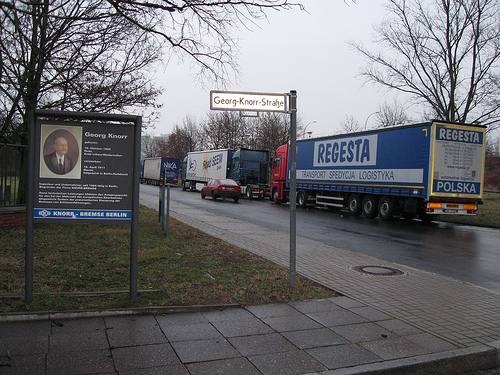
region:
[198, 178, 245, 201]
car on street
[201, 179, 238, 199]
red car on street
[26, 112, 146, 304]
sign on grass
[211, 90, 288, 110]
street sign on corner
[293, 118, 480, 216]
trailer on 18 wheeler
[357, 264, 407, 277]
man hole in ground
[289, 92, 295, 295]
street sign pole on corner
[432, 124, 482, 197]
back of 18 wheeler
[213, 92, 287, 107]
white street sign on corner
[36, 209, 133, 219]
blue color on sign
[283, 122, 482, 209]
blue and white trailer of truck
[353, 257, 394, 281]
manhole cover on sidewalk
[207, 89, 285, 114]
black lettering on white street sign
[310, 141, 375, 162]
blue lettering on white background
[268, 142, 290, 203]
red cab of truck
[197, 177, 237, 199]
red car driving down the road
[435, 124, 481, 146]
white lettering on blue background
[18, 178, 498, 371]
sidewalk along the street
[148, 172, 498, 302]
streets trucks and car are on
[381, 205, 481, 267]
reflection of truck on street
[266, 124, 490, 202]
a red and blue semi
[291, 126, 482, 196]
a blue and white trailer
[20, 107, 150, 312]
a brown and white sign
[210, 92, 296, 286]
a sign on a pole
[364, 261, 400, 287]
a man hole cover on the ground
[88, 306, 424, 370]
a wet side walk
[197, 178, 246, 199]
a red car on the street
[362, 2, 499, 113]
a leafless tree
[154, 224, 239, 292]
green and brown grass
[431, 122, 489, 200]
a yellow edge on a door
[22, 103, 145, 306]
Sign with the history of Georg Knorr.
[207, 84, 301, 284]
Street sign saying "Georg-Knorr-Strasse."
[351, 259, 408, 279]
Circular manhole cover on sidewalk.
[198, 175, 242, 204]
Red car going down street.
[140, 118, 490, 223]
Group of moving vans on parked on side of road,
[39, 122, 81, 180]
Picture of Georg Knorr on sign.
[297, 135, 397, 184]
Regesta Transport Spedycja Logistyka.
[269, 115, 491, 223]
Blue and red moving truck from Poland.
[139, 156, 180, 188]
Blue and white Nika moving truck.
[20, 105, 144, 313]
Historic information sign of Georg Knorr.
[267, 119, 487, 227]
A truck with a red cab.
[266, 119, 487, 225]
A blue, white, and red semi truck.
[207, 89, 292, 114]
A rectangular white sign.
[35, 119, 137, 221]
Information about Georg Knorr.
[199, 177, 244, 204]
A small red car.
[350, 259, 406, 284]
A circle on the sidewalk.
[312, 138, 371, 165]
The word regesta in blue letters.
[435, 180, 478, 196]
The word Polska in white letters.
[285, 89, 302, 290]
A metal sign pole.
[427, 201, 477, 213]
Orange reflective paint on the back of a truck.